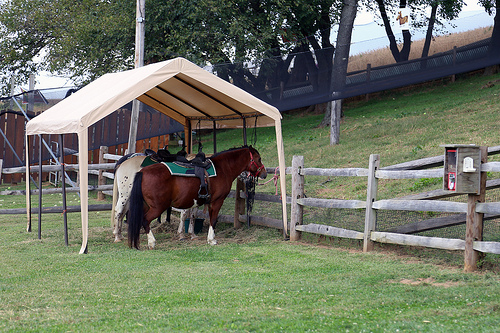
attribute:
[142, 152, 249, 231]
horse — brown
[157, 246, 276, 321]
grass — green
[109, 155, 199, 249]
horse — white, standing, under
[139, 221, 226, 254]
feet — white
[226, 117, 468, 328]
fences — wood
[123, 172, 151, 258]
tail — black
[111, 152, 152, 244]
horse — white, brown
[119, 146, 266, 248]
horse — brown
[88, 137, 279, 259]
horses — standing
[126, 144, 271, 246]
horse — red, standing, under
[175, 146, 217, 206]
saddle — green 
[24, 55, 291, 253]
tent — white, over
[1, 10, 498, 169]
mesh — black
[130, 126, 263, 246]
horse — white, standing, red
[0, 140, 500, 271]
fence — wood, wodden, around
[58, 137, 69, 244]
pole — metal, gray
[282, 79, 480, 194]
slope — grassy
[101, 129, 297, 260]
horse — white, black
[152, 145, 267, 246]
horse — red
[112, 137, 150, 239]
horse — white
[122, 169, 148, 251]
tail — black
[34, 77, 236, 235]
shelter — white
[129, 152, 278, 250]
horse — brown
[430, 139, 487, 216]
box — wooden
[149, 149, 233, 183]
back — horse's 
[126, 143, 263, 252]
horse — tied